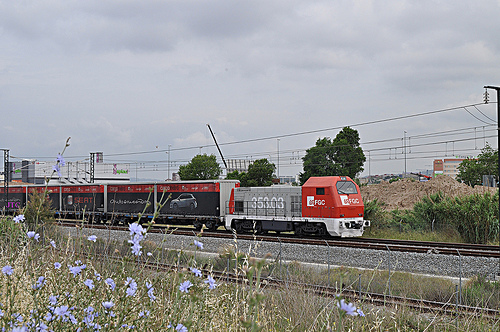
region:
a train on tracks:
[53, 95, 494, 325]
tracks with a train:
[179, 132, 410, 328]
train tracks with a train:
[193, 120, 419, 285]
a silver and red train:
[229, 134, 410, 280]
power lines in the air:
[305, 75, 487, 196]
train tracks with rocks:
[219, 155, 479, 314]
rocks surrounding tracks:
[372, 198, 479, 303]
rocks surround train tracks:
[324, 193, 489, 318]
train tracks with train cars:
[171, 132, 479, 297]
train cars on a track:
[100, 89, 475, 330]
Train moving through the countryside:
[2, 130, 427, 291]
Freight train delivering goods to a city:
[1, 143, 432, 273]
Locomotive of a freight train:
[226, 166, 376, 243]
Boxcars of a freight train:
[5, 170, 241, 230]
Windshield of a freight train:
[330, 175, 365, 197]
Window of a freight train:
[310, 180, 330, 200]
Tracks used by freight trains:
[370, 230, 495, 262]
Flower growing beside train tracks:
[110, 215, 160, 280]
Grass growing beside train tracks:
[280, 252, 418, 307]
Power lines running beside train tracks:
[392, 96, 480, 170]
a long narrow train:
[46, 171, 383, 253]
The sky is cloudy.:
[42, 10, 327, 97]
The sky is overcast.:
[80, 20, 290, 105]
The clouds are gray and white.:
[50, 19, 327, 119]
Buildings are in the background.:
[1, 143, 136, 203]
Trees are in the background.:
[193, 120, 384, 187]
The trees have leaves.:
[177, 123, 362, 190]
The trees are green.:
[176, 121, 369, 180]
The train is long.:
[2, 156, 372, 253]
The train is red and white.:
[202, 165, 379, 244]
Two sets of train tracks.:
[371, 225, 496, 323]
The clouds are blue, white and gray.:
[66, 22, 298, 92]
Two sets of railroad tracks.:
[373, 232, 498, 327]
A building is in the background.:
[1, 125, 137, 229]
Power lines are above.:
[368, 77, 498, 162]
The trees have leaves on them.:
[178, 120, 375, 195]